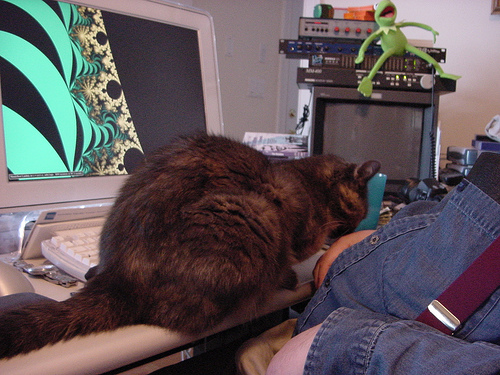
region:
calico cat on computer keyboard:
[0, 135, 395, 360]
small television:
[295, 84, 437, 183]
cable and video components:
[279, 16, 458, 93]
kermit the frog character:
[355, 0, 457, 95]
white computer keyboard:
[43, 225, 108, 280]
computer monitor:
[0, 0, 218, 207]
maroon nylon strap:
[422, 242, 499, 334]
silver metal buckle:
[428, 301, 460, 331]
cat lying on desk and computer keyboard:
[0, 133, 382, 358]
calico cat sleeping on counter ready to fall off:
[2, 134, 379, 373]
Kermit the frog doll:
[354, 1, 459, 101]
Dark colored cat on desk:
[2, 130, 379, 317]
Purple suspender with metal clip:
[409, 224, 494, 333]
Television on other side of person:
[305, 76, 437, 179]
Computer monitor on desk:
[0, 3, 227, 168]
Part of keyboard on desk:
[45, 230, 108, 276]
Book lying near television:
[244, 129, 312, 159]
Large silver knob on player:
[417, 74, 435, 89]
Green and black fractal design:
[5, 7, 107, 180]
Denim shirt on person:
[280, 175, 494, 371]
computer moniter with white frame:
[0, 1, 223, 211]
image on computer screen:
[2, 1, 208, 182]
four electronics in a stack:
[277, 15, 456, 87]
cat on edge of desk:
[2, 131, 384, 346]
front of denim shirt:
[294, 180, 496, 372]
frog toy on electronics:
[356, 0, 458, 97]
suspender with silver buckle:
[415, 241, 498, 333]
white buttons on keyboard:
[41, 226, 101, 278]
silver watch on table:
[14, 259, 76, 285]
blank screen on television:
[316, 90, 439, 176]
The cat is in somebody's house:
[0, 30, 497, 340]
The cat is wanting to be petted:
[30, 18, 471, 349]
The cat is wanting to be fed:
[31, 51, 473, 371]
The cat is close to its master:
[45, 56, 488, 362]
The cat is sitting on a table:
[21, 72, 446, 358]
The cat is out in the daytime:
[30, 50, 458, 350]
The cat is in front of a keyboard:
[5, 47, 465, 372]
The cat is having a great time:
[38, 80, 453, 348]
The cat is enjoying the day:
[12, 68, 450, 352]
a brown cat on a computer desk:
[2, 138, 380, 363]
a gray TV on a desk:
[311, 88, 439, 203]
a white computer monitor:
[0, 0, 225, 218]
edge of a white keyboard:
[39, 220, 104, 284]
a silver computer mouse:
[1, 259, 33, 296]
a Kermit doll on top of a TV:
[355, 0, 460, 101]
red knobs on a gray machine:
[333, 25, 373, 34]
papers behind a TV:
[243, 130, 307, 159]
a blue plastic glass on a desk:
[358, 172, 388, 233]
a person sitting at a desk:
[236, 153, 499, 373]